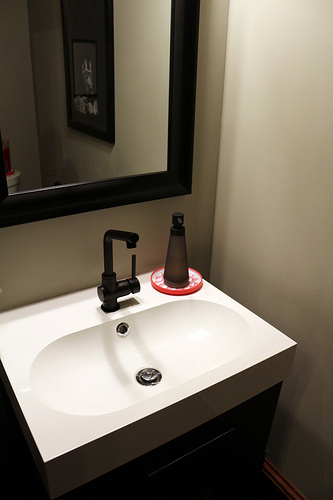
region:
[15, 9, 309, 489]
photograph taken in a bathroom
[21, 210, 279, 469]
white sink with black faucet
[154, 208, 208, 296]
black soap dispenser on white sink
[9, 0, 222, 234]
mirror with black frame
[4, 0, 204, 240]
mirror hung above sink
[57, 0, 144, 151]
reflection of wall art in mirror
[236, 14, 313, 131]
walls painted solid white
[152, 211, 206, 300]
red and white dish under soap dispenser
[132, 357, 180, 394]
silver drain in whie sink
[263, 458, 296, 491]
wooden baseboard along wall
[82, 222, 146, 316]
brown metal faucet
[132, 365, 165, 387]
round silver drain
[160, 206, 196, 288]
brown soap pump container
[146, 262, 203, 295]
round red and white platform underneath brown soap pump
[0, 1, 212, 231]
brown framed mirror on wall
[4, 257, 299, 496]
white square shaped sink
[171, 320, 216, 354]
white light reflected in sink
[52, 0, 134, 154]
picture hanging on wall reflected in mirror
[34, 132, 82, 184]
black shadow on wall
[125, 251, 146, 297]
handle on metal faucet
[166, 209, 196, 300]
soap dispenser on the sink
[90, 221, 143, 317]
black faucet in the bathroom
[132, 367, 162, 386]
silver drain in the sink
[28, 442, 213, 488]
brown sink in the bathroom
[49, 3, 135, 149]
picture on the wall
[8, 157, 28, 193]
toilet in the bathroom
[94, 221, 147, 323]
black faucet for water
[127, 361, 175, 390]
chrome sink drain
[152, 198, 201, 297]
brown bottle of soap dispenser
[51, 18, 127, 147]
large picture on the wall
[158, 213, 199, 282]
A sosp dish on the sink.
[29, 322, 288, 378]
The sink is white.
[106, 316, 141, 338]
A small hole in the sink.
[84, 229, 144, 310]
Faucet above the sink.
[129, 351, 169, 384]
Drainer in the sink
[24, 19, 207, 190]
A mirror above the sink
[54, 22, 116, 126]
Reflection of a picture on wall in the mirror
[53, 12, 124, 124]
A picture on the wall.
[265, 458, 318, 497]
Molding on the floor.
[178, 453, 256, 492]
Cabinet under the sink.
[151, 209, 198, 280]
black bottle on counter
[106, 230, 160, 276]
black faucet on sinck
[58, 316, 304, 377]
white top on sink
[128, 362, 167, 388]
silver drain in sinck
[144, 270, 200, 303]
coaster under black botter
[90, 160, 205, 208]
black rim on mirror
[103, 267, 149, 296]
black pipe on faucet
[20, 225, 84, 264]
tan paint on wall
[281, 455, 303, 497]
wood trim on floor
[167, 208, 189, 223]
black cap on bottle